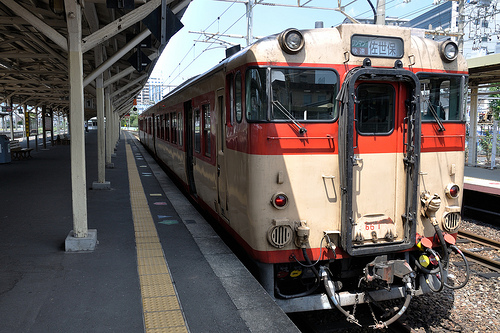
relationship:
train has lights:
[134, 22, 476, 331] [279, 26, 461, 64]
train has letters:
[134, 22, 476, 331] [348, 31, 407, 60]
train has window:
[134, 22, 476, 331] [353, 77, 399, 138]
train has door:
[134, 22, 476, 331] [334, 65, 420, 257]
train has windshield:
[134, 22, 476, 331] [247, 64, 474, 124]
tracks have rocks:
[458, 220, 498, 282] [406, 214, 498, 330]